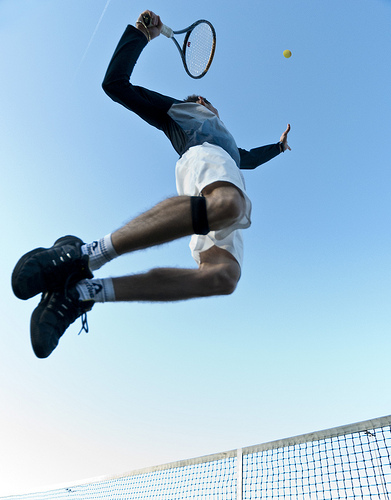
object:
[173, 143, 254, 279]
shorts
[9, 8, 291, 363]
player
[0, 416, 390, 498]
net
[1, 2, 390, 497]
sky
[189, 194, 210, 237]
band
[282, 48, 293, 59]
ball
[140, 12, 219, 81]
racket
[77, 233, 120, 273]
socks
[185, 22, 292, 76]
hit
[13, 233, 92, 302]
sneakers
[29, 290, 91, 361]
sneaker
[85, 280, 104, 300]
design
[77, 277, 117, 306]
sock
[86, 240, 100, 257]
design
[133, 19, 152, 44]
bracelet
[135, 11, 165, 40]
hand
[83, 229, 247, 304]
legs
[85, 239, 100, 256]
logo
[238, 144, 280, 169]
sleaves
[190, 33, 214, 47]
string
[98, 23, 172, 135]
sleaves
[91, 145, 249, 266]
leg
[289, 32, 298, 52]
air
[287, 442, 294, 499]
string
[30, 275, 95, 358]
left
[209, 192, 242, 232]
knee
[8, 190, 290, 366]
jumping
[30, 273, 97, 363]
feet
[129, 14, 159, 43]
wrist